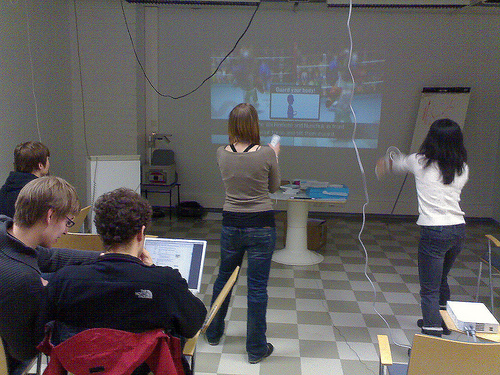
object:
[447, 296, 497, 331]
game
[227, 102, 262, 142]
hair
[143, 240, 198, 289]
screen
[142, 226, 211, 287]
laptop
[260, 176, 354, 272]
table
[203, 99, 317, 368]
girl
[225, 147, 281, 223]
shirt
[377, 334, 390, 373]
wooden arm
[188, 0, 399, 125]
image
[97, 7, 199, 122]
wall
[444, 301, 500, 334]
projector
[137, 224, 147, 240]
ear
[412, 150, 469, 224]
shirt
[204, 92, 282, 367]
woman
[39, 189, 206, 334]
man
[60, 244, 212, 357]
black jacket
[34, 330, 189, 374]
coat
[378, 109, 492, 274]
girl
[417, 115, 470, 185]
black hair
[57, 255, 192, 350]
jacket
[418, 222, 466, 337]
jeans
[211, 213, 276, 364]
jeans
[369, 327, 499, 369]
desk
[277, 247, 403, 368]
floor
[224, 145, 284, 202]
sweater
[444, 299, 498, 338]
wii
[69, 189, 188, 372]
boy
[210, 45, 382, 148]
video game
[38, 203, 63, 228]
ear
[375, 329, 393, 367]
arm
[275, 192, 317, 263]
base